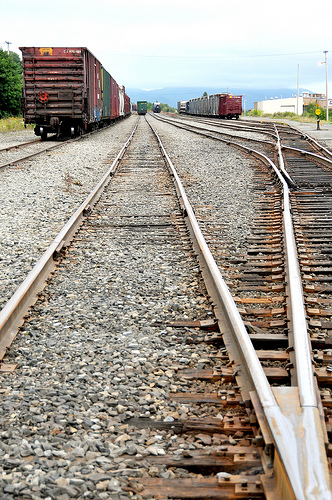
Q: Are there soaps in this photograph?
A: No, there are no soaps.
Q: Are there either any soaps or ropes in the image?
A: No, there are no soaps or ropes.